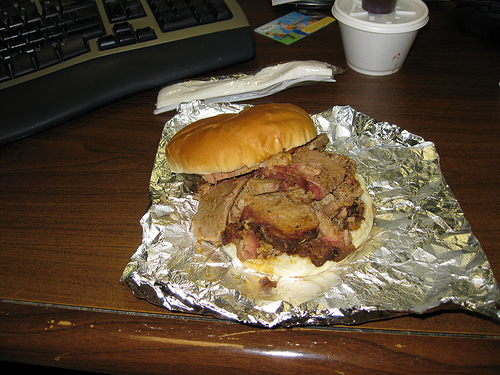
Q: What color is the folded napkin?
A: White.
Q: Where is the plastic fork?
A: Next to the napkin.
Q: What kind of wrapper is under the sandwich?
A: Aluminum foil.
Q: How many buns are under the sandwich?
A: One.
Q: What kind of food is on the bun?
A: Meat.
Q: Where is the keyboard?
A: Left of the food.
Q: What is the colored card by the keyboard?
A: A credit card.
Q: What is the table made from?
A: Wood.